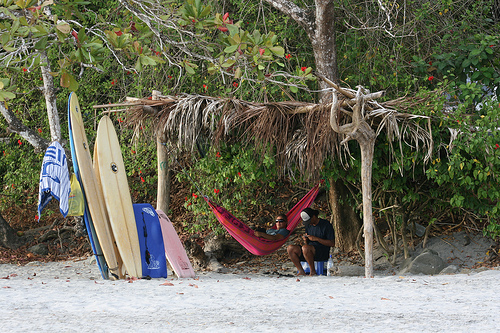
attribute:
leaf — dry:
[390, 110, 401, 143]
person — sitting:
[284, 206, 337, 276]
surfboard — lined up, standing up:
[95, 109, 140, 279]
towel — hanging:
[32, 137, 72, 219]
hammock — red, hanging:
[169, 143, 326, 255]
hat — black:
[295, 206, 321, 223]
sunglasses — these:
[272, 219, 287, 224]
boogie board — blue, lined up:
[65, 89, 113, 281]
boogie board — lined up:
[150, 206, 198, 278]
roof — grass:
[87, 91, 436, 185]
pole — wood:
[330, 86, 393, 278]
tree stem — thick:
[307, 1, 361, 261]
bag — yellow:
[62, 167, 88, 219]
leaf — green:
[263, 44, 286, 59]